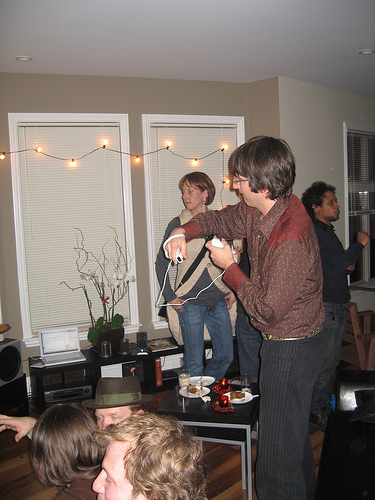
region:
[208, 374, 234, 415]
two lite red candles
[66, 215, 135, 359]
sticks with a red bow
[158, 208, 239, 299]
hands holding a game controller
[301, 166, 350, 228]
profile of man with goatee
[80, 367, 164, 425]
hat with a green band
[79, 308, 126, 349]
houseplant with green leaves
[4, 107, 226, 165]
holiday lights on a window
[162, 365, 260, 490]
small table with dirty plates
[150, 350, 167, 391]
book with red cover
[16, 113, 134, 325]
closed venetian blinds on a window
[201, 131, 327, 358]
person holding game control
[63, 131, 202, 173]
white lights on wire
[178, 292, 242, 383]
blue jeans on woman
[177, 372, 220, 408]
white plates on table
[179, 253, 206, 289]
black strap of purse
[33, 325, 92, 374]
open laptop on table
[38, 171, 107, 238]
closed white blinds on window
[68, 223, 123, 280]
bare branches in front of window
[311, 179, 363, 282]
man in gray shirt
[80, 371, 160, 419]
hat on man's head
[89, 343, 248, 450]
the table is black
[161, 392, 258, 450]
the table is black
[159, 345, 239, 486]
the table is black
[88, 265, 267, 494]
the table is black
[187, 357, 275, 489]
the table is black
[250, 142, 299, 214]
Person has brown hair.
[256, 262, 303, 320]
Person is weaing red patterned shirt.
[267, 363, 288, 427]
Person is wearing black pants.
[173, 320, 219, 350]
Person is wearing blue jeans.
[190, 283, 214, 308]
Person is wearing gray shirt.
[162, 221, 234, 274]
Person is holding wii remote.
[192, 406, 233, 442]
Black table in room.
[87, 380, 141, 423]
Man is wearing brown hat.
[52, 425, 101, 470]
Person has brown hair.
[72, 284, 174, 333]
Plant in black pot near window.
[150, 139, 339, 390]
man playing video games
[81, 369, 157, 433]
man wearing grown and green fedora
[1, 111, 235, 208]
string lights are lit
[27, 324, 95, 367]
small white computer laptop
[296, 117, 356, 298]
man with curly hair and facial hair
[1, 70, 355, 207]
walls are painted medium beige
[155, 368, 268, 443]
food and drinks on coffee table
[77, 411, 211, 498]
man has blond hair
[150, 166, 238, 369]
woman wears beige fleece and blue jeans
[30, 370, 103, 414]
black electronic device on furniture